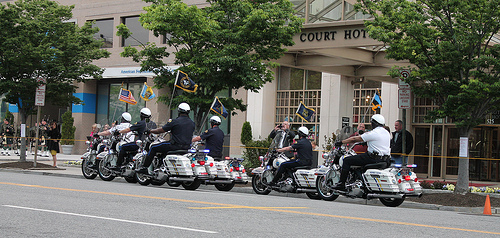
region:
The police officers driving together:
[73, 71, 428, 208]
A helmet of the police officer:
[367, 111, 387, 129]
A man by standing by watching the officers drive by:
[393, 116, 413, 161]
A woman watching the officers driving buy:
[36, 117, 68, 171]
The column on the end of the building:
[60, 71, 103, 155]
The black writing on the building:
[291, 25, 383, 42]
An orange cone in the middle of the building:
[476, 191, 496, 219]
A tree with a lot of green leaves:
[128, 3, 301, 85]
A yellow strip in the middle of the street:
[29, 179, 243, 215]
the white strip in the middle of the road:
[3, 197, 163, 235]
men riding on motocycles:
[77, 98, 425, 212]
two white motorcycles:
[249, 111, 425, 203]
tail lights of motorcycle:
[394, 166, 420, 196]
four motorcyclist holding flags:
[78, 69, 250, 196]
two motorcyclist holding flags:
[247, 91, 430, 208]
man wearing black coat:
[388, 116, 415, 161]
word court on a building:
[295, 26, 343, 45]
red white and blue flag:
[117, 86, 137, 106]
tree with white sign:
[416, 4, 477, 192]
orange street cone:
[477, 189, 495, 219]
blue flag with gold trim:
[172, 72, 199, 97]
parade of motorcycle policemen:
[81, 108, 433, 206]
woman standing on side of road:
[43, 118, 62, 168]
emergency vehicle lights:
[394, 167, 406, 188]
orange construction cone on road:
[479, 194, 492, 215]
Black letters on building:
[294, 25, 372, 44]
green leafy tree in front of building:
[166, 0, 291, 76]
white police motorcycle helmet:
[175, 103, 191, 113]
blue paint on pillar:
[72, 90, 94, 113]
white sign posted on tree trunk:
[458, 133, 468, 161]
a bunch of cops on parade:
[78, 60, 410, 202]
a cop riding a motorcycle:
[309, 100, 429, 211]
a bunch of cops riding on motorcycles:
[71, 43, 440, 213]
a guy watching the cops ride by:
[383, 116, 418, 168]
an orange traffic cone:
[479, 193, 497, 217]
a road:
[10, 172, 426, 236]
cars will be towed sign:
[21, 66, 54, 120]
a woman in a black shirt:
[38, 116, 65, 174]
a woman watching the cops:
[37, 113, 71, 179]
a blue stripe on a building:
[0, 79, 109, 115]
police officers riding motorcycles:
[76, 98, 428, 207]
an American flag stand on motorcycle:
[77, 65, 138, 182]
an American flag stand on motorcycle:
[317, 86, 412, 210]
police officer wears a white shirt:
[330, 111, 395, 203]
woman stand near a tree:
[42, 117, 66, 172]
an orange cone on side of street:
[479, 192, 498, 221]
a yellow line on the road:
[25, 177, 188, 203]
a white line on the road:
[6, 202, 143, 237]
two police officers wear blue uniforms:
[142, 100, 229, 183]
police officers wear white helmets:
[81, 100, 394, 196]